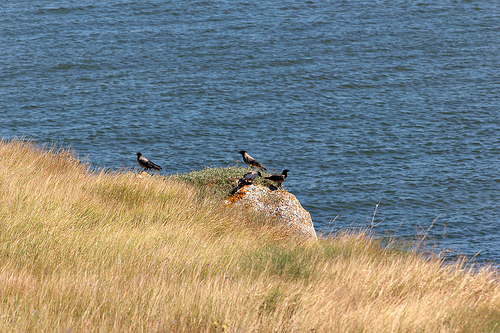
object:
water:
[0, 1, 498, 144]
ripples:
[342, 81, 350, 85]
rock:
[164, 166, 318, 245]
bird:
[238, 149, 266, 172]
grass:
[0, 192, 227, 332]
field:
[1, 143, 499, 332]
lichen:
[134, 150, 163, 175]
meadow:
[2, 150, 496, 333]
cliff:
[164, 165, 322, 251]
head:
[237, 149, 248, 154]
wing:
[247, 157, 257, 165]